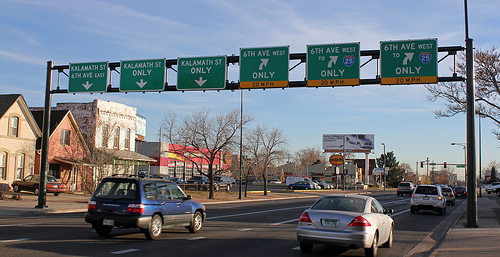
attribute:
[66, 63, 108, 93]
sign — `green, square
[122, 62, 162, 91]
sign — green, square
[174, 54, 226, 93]
sign — green, square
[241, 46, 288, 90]
sign — green, square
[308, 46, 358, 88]
sign — green, square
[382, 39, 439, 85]
sign — green, square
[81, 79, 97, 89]
arrow — white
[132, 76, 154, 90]
arrow — white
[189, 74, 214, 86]
arrow — white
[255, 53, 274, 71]
arrow — white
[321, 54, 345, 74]
sign — rectangular , green , white, yellow, traffic sign 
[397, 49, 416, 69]
arrow — white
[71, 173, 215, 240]
car — blue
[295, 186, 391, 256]
car — grey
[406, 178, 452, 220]
car — white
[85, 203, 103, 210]
tail light — red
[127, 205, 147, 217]
tail light — red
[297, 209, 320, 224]
tail light — red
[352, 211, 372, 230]
tail light — red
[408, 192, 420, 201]
tail light — red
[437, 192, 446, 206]
tail light — red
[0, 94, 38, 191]
house — tan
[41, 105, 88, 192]
house — beige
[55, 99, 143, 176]
building — white